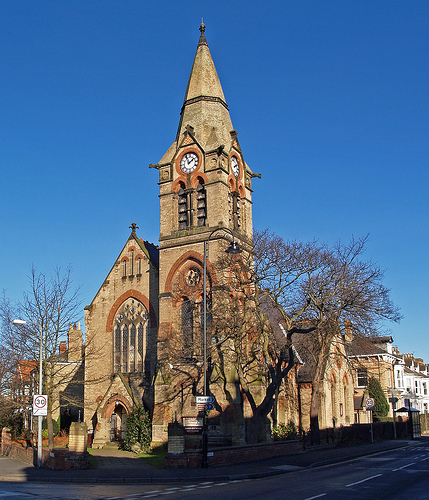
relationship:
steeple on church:
[198, 18, 205, 31] [80, 18, 393, 459]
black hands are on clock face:
[185, 152, 196, 166] [179, 151, 201, 174]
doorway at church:
[106, 407, 132, 443] [80, 18, 355, 457]